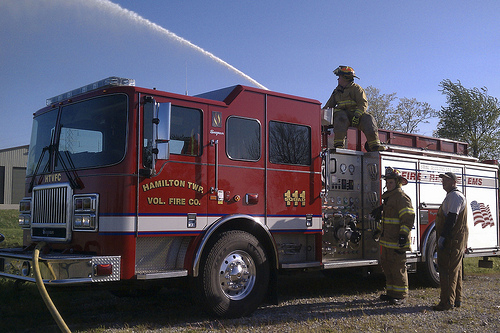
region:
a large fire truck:
[0, 75, 497, 315]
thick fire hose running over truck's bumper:
[32, 236, 73, 331]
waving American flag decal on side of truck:
[468, 198, 493, 226]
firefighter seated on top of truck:
[320, 62, 385, 148]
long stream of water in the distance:
[81, 0, 271, 90]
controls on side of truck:
[320, 147, 365, 258]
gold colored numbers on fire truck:
[280, 185, 305, 205]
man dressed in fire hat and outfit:
[370, 165, 415, 305]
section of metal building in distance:
[1, 143, 30, 211]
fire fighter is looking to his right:
[334, 64, 359, 94]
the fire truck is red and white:
[6, 64, 499, 288]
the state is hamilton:
[135, 167, 211, 209]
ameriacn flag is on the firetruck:
[471, 199, 495, 236]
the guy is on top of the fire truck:
[326, 67, 384, 161]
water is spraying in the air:
[121, 13, 260, 83]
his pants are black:
[426, 214, 465, 315]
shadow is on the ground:
[292, 283, 354, 332]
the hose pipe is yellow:
[26, 255, 71, 332]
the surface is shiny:
[46, 258, 87, 285]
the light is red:
[98, 260, 112, 276]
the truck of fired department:
[16, 85, 498, 272]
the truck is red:
[18, 81, 496, 299]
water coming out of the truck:
[79, 3, 291, 94]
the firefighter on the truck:
[307, 60, 389, 146]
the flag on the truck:
[468, 192, 493, 233]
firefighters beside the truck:
[375, 158, 470, 305]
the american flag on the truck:
[463, 198, 499, 228]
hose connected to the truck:
[31, 234, 81, 331]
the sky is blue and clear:
[261, 11, 474, 61]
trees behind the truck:
[377, 80, 499, 132]